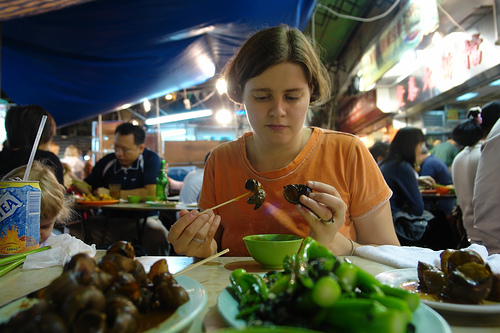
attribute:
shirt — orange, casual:
[195, 126, 394, 261]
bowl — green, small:
[243, 232, 305, 271]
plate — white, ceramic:
[373, 266, 499, 316]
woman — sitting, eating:
[165, 24, 404, 260]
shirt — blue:
[376, 157, 435, 241]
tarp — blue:
[0, 0, 318, 135]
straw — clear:
[23, 110, 51, 180]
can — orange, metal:
[0, 175, 43, 258]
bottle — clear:
[156, 156, 172, 203]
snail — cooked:
[149, 254, 175, 283]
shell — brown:
[281, 183, 314, 208]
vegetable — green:
[314, 274, 343, 308]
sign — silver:
[375, 17, 499, 116]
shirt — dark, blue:
[83, 147, 166, 216]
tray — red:
[417, 187, 440, 196]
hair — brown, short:
[224, 23, 334, 110]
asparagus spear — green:
[349, 265, 421, 310]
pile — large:
[1, 241, 192, 332]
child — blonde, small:
[1, 162, 93, 248]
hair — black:
[380, 126, 428, 174]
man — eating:
[79, 120, 173, 256]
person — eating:
[376, 125, 457, 249]